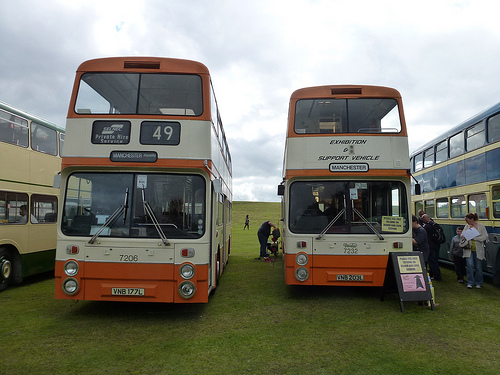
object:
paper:
[462, 227, 480, 241]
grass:
[0, 303, 499, 374]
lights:
[64, 260, 79, 277]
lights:
[62, 277, 79, 295]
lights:
[179, 263, 195, 279]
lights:
[178, 281, 196, 299]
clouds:
[6, 7, 60, 80]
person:
[458, 213, 489, 289]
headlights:
[62, 260, 79, 295]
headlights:
[178, 263, 196, 299]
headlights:
[295, 253, 310, 282]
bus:
[410, 102, 500, 288]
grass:
[2, 207, 496, 372]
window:
[61, 171, 206, 239]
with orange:
[281, 84, 413, 287]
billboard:
[380, 251, 435, 313]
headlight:
[295, 253, 309, 266]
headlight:
[295, 266, 309, 281]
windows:
[0, 188, 29, 225]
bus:
[0, 102, 68, 292]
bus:
[53, 57, 232, 303]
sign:
[110, 150, 158, 163]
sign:
[329, 162, 369, 172]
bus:
[277, 84, 420, 286]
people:
[421, 213, 446, 281]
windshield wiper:
[142, 189, 171, 245]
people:
[449, 227, 471, 283]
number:
[153, 126, 173, 141]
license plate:
[111, 287, 144, 296]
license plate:
[336, 274, 364, 281]